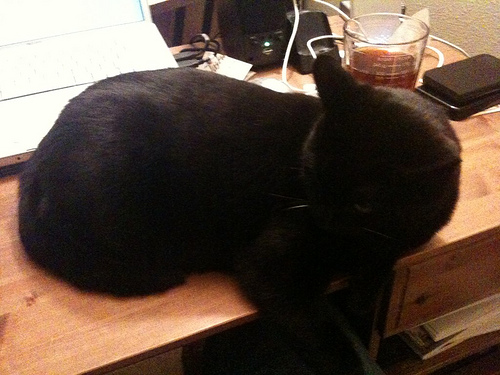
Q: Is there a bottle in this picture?
A: No, there are no bottles.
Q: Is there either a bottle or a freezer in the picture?
A: No, there are no bottles or refrigerators.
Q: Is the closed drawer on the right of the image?
A: Yes, the drawer is on the right of the image.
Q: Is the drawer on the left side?
A: No, the drawer is on the right of the image.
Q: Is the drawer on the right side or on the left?
A: The drawer is on the right of the image.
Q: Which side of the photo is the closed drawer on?
A: The drawer is on the right of the image.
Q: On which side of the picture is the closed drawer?
A: The drawer is on the right of the image.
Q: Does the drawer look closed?
A: Yes, the drawer is closed.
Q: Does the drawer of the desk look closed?
A: Yes, the drawer is closed.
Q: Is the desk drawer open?
A: No, the drawer is closed.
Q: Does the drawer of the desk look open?
A: No, the drawer is closed.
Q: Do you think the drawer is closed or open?
A: The drawer is closed.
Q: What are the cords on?
A: The cords are on the desk.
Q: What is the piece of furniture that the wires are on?
A: The piece of furniture is a desk.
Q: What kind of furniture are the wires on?
A: The wires are on the desk.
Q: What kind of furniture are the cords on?
A: The wires are on the desk.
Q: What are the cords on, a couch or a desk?
A: The cords are on a desk.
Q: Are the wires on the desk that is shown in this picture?
A: Yes, the wires are on the desk.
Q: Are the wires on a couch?
A: No, the wires are on the desk.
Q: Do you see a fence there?
A: No, there are no fences.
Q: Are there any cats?
A: Yes, there is a cat.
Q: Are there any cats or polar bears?
A: Yes, there is a cat.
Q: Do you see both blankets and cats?
A: No, there is a cat but no blankets.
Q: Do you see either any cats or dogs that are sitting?
A: Yes, the cat is sitting.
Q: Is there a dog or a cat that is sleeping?
A: Yes, the cat is sleeping.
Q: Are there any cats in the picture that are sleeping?
A: Yes, there is a cat that is sleeping.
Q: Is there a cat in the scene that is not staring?
A: Yes, there is a cat that is sleeping.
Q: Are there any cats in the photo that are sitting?
A: Yes, there is a cat that is sitting.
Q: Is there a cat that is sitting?
A: Yes, there is a cat that is sitting.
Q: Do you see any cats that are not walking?
A: Yes, there is a cat that is sitting .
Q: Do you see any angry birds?
A: No, there are no angry birds.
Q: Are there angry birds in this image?
A: No, there are no angry birds.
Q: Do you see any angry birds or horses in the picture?
A: No, there are no angry birds or horses.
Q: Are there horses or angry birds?
A: No, there are no angry birds or horses.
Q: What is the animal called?
A: The animal is a cat.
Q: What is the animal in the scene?
A: The animal is a cat.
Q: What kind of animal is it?
A: The animal is a cat.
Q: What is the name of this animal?
A: This is a cat.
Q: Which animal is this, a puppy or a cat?
A: This is a cat.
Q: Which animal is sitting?
A: The animal is a cat.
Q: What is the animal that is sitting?
A: The animal is a cat.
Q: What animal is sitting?
A: The animal is a cat.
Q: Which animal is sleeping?
A: The animal is a cat.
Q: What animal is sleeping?
A: The animal is a cat.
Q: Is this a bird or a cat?
A: This is a cat.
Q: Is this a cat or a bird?
A: This is a cat.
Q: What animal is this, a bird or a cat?
A: This is a cat.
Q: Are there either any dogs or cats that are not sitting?
A: No, there is a cat but it is sitting.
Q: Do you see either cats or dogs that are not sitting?
A: No, there is a cat but it is sitting.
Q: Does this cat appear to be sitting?
A: Yes, the cat is sitting.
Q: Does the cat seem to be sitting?
A: Yes, the cat is sitting.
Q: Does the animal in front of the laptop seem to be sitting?
A: Yes, the cat is sitting.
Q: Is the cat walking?
A: No, the cat is sitting.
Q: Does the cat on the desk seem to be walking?
A: No, the cat is sitting.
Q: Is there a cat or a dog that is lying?
A: No, there is a cat but it is sitting.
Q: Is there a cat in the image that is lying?
A: No, there is a cat but it is sitting.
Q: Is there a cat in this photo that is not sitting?
A: No, there is a cat but it is sitting.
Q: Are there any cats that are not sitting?
A: No, there is a cat but it is sitting.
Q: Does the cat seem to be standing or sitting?
A: The cat is sitting.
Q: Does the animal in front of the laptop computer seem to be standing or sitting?
A: The cat is sitting.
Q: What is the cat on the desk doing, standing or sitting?
A: The cat is sitting.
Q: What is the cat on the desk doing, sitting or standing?
A: The cat is sitting.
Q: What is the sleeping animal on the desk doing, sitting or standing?
A: The cat is sitting.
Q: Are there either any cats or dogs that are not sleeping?
A: No, there is a cat but it is sleeping.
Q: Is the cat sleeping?
A: Yes, the cat is sleeping.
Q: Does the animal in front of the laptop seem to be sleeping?
A: Yes, the cat is sleeping.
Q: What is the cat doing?
A: The cat is sleeping.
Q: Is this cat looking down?
A: No, the cat is sleeping.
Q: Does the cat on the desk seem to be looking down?
A: No, the cat is sleeping.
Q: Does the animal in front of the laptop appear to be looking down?
A: No, the cat is sleeping.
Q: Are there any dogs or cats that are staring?
A: No, there is a cat but it is sleeping.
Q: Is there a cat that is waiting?
A: No, there is a cat but it is sleeping.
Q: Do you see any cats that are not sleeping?
A: No, there is a cat but it is sleeping.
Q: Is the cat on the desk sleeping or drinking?
A: The cat is sleeping.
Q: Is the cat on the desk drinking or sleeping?
A: The cat is sleeping.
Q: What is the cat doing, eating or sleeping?
A: The cat is sleeping.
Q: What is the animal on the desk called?
A: The animal is a cat.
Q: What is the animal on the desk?
A: The animal is a cat.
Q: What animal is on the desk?
A: The animal is a cat.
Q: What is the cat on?
A: The cat is on the desk.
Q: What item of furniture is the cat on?
A: The cat is on the desk.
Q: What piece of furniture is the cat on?
A: The cat is on the desk.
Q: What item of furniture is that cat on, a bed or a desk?
A: The cat is on a desk.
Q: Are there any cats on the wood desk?
A: Yes, there is a cat on the desk.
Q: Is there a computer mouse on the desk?
A: No, there is a cat on the desk.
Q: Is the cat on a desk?
A: Yes, the cat is on a desk.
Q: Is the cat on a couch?
A: No, the cat is on a desk.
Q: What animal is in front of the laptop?
A: The cat is in front of the laptop.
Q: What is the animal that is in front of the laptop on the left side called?
A: The animal is a cat.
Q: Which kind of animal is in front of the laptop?
A: The animal is a cat.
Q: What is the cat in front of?
A: The cat is in front of the laptop.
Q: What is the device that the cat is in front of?
A: The device is a laptop.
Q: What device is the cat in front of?
A: The cat is in front of the laptop.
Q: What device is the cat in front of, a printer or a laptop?
A: The cat is in front of a laptop.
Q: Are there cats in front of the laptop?
A: Yes, there is a cat in front of the laptop.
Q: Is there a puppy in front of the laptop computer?
A: No, there is a cat in front of the laptop computer.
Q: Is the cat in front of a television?
A: No, the cat is in front of a laptop.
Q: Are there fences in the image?
A: No, there are no fences.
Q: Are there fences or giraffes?
A: No, there are no fences or giraffes.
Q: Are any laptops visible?
A: Yes, there is a laptop.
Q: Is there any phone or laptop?
A: Yes, there is a laptop.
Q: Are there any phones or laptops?
A: Yes, there is a laptop.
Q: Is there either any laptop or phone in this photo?
A: Yes, there is a laptop.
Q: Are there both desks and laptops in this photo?
A: Yes, there are both a laptop and a desk.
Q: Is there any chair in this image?
A: No, there are no chairs.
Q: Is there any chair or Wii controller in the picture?
A: No, there are no chairs or Wii controllers.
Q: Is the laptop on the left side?
A: Yes, the laptop is on the left of the image.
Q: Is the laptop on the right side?
A: No, the laptop is on the left of the image.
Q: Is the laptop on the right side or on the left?
A: The laptop is on the left of the image.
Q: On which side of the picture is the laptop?
A: The laptop is on the left of the image.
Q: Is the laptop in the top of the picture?
A: Yes, the laptop is in the top of the image.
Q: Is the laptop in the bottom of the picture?
A: No, the laptop is in the top of the image.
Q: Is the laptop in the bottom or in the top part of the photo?
A: The laptop is in the top of the image.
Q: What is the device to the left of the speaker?
A: The device is a laptop.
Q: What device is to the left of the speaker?
A: The device is a laptop.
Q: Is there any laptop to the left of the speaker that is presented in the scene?
A: Yes, there is a laptop to the left of the speaker.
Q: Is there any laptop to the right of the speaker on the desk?
A: No, the laptop is to the left of the speaker.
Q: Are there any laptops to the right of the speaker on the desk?
A: No, the laptop is to the left of the speaker.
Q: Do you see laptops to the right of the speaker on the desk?
A: No, the laptop is to the left of the speaker.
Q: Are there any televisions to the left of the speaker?
A: No, there is a laptop to the left of the speaker.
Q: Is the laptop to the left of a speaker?
A: Yes, the laptop is to the left of a speaker.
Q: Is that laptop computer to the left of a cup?
A: No, the laptop computer is to the left of a speaker.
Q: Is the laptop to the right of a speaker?
A: No, the laptop is to the left of a speaker.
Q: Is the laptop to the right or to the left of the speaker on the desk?
A: The laptop is to the left of the speaker.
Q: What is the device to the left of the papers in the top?
A: The device is a laptop.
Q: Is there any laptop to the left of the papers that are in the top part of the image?
A: Yes, there is a laptop to the left of the papers.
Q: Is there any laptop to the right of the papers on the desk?
A: No, the laptop is to the left of the papers.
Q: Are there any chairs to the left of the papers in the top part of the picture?
A: No, there is a laptop to the left of the papers.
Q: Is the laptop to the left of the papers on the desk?
A: Yes, the laptop is to the left of the papers.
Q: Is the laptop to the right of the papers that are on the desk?
A: No, the laptop is to the left of the papers.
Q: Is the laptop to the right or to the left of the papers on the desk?
A: The laptop is to the left of the papers.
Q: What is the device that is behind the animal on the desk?
A: The device is a laptop.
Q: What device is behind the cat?
A: The device is a laptop.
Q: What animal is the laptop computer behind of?
A: The laptop computer is behind the cat.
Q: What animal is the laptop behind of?
A: The laptop computer is behind the cat.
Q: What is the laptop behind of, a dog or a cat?
A: The laptop is behind a cat.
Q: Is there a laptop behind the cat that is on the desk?
A: Yes, there is a laptop behind the cat.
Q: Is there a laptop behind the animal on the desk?
A: Yes, there is a laptop behind the cat.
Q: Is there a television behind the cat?
A: No, there is a laptop behind the cat.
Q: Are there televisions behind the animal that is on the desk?
A: No, there is a laptop behind the cat.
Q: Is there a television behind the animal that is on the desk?
A: No, there is a laptop behind the cat.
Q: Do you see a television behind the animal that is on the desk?
A: No, there is a laptop behind the cat.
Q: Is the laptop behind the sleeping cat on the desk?
A: Yes, the laptop is behind the cat.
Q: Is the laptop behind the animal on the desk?
A: Yes, the laptop is behind the cat.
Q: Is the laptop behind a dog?
A: No, the laptop is behind the cat.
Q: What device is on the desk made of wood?
A: The device is a laptop.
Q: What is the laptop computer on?
A: The laptop computer is on the desk.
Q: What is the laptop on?
A: The laptop computer is on the desk.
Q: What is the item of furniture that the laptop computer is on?
A: The piece of furniture is a desk.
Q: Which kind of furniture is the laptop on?
A: The laptop computer is on the desk.